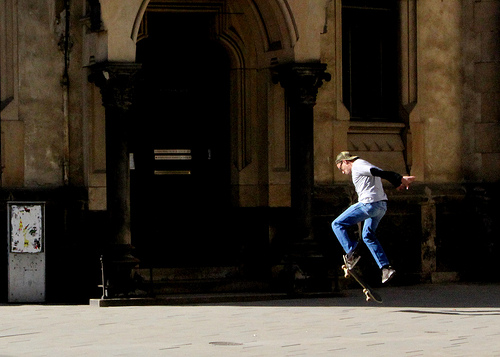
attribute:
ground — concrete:
[145, 305, 404, 349]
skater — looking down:
[329, 148, 416, 284]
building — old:
[1, 1, 481, 288]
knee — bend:
[329, 217, 350, 230]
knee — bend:
[359, 230, 374, 241]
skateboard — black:
[339, 250, 385, 303]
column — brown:
[82, 57, 151, 294]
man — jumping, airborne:
[329, 147, 417, 282]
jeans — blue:
[328, 200, 387, 268]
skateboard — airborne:
[338, 254, 387, 308]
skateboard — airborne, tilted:
[339, 256, 384, 306]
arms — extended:
[371, 166, 416, 192]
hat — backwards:
[333, 147, 360, 161]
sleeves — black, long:
[363, 168, 403, 185]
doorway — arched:
[119, 25, 259, 287]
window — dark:
[336, 3, 414, 129]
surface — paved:
[2, 288, 480, 355]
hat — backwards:
[328, 148, 361, 164]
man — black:
[327, 145, 420, 288]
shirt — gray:
[346, 151, 390, 203]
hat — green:
[333, 149, 360, 164]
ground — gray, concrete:
[3, 281, 483, 354]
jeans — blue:
[328, 201, 395, 270]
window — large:
[336, 2, 408, 124]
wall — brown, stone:
[412, 4, 466, 187]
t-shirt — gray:
[348, 154, 389, 206]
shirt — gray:
[348, 156, 391, 206]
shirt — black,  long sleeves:
[346, 156, 389, 205]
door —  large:
[130, 11, 239, 281]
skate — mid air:
[300, 134, 396, 264]